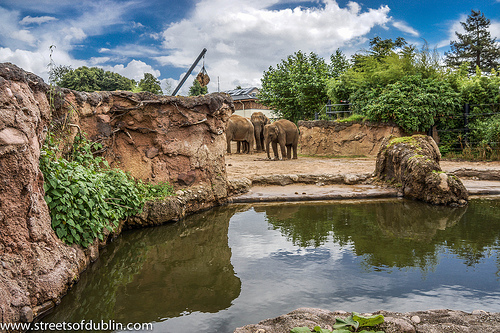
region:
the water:
[245, 181, 350, 328]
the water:
[184, 214, 298, 319]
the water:
[275, 244, 336, 305]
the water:
[230, 191, 324, 288]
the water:
[174, 204, 279, 275]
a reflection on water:
[116, 216, 257, 328]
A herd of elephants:
[226, 104, 305, 164]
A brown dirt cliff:
[22, 58, 231, 268]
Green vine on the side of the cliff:
[25, 120, 158, 240]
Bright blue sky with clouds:
[85, 11, 312, 82]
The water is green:
[175, 193, 440, 318]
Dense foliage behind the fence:
[289, 53, 483, 148]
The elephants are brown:
[217, 95, 312, 180]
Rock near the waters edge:
[356, 127, 471, 224]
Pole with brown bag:
[156, 32, 232, 94]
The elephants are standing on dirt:
[226, 103, 321, 173]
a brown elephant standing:
[220, 105, 255, 155]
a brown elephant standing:
[242, 106, 267, 146]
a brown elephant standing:
[258, 120, 302, 161]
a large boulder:
[366, 134, 464, 206]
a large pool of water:
[59, 187, 497, 329]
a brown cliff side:
[0, 79, 227, 318]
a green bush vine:
[43, 134, 152, 252]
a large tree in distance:
[265, 60, 317, 119]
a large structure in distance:
[215, 81, 269, 111]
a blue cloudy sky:
[3, 0, 491, 91]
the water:
[158, 250, 233, 281]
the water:
[200, 268, 342, 329]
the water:
[122, 194, 313, 268]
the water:
[197, 282, 272, 323]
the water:
[217, 240, 284, 304]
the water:
[185, 178, 306, 285]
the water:
[190, 178, 270, 243]